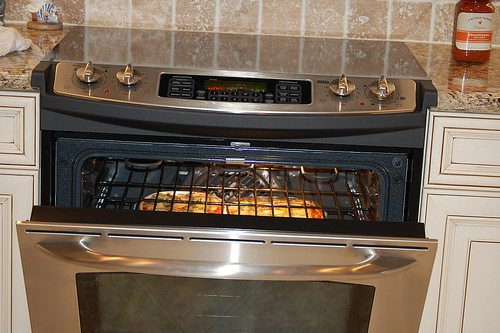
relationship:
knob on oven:
[298, 65, 362, 110] [16, 25, 440, 331]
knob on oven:
[369, 74, 396, 101] [16, 25, 440, 331]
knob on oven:
[329, 73, 355, 97] [16, 25, 440, 331]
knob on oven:
[72, 58, 104, 87] [12, 57, 442, 332]